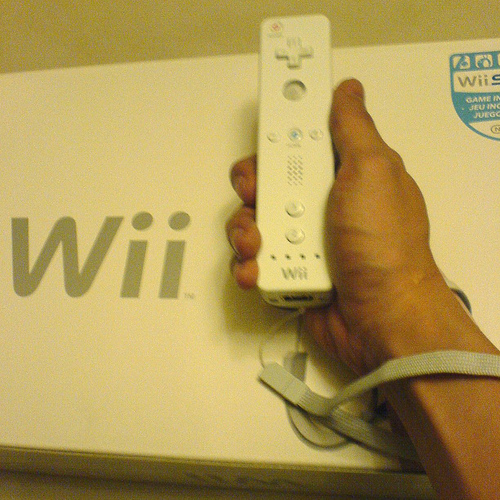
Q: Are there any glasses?
A: No, there are no glasses.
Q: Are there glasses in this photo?
A: No, there are no glasses.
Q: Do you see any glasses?
A: No, there are no glasses.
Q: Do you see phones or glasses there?
A: No, there are no glasses or phones.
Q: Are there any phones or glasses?
A: No, there are no glasses or phones.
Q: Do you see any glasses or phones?
A: No, there are no glasses or phones.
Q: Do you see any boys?
A: No, there are no boys.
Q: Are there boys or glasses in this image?
A: No, there are no boys or glasses.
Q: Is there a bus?
A: No, there are no buses.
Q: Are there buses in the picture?
A: No, there are no buses.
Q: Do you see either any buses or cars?
A: No, there are no buses or cars.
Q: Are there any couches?
A: No, there are no couches.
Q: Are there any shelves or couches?
A: No, there are no couches or shelves.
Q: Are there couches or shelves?
A: No, there are no couches or shelves.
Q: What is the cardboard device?
A: The device is a Wii.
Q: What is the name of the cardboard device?
A: The device is a Wii.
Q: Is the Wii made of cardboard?
A: Yes, the Wii is made of cardboard.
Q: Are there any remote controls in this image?
A: Yes, there is a remote control.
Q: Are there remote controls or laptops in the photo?
A: Yes, there is a remote control.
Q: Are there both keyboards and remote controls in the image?
A: No, there is a remote control but no keyboards.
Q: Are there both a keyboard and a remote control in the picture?
A: No, there is a remote control but no keyboards.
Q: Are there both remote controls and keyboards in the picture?
A: No, there is a remote control but no keyboards.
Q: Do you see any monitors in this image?
A: No, there are no monitors.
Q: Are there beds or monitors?
A: No, there are no monitors or beds.